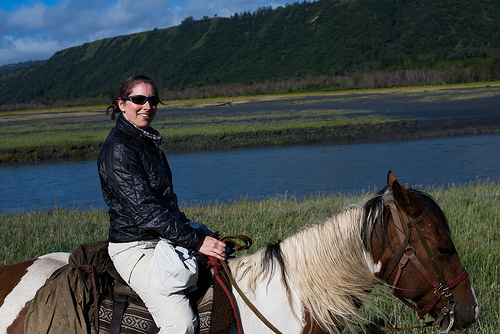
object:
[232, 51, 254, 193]
horse's mane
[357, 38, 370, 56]
trees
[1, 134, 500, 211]
water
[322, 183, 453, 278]
hair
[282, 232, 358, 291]
white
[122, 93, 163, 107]
sunglasses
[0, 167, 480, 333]
horse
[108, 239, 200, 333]
pants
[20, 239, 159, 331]
blanket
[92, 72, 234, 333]
woman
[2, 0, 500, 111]
mountain